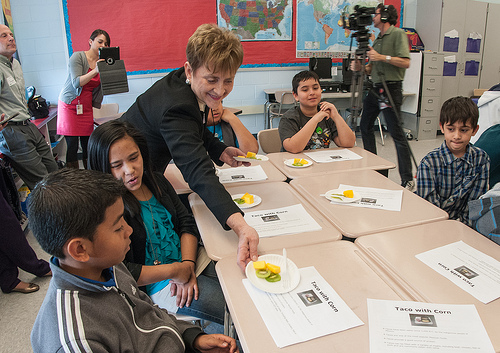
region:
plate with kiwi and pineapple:
[252, 247, 297, 291]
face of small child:
[99, 217, 149, 264]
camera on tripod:
[350, 2, 383, 67]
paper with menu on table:
[262, 296, 359, 333]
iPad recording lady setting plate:
[94, 38, 137, 86]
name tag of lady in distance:
[70, 100, 90, 112]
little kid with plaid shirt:
[425, 70, 472, 208]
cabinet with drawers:
[419, 51, 446, 118]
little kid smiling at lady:
[271, 61, 357, 142]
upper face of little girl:
[86, 125, 154, 175]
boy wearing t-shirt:
[272, 68, 358, 150]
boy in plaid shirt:
[415, 96, 495, 226]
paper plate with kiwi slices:
[239, 248, 306, 298]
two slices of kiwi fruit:
[253, 263, 283, 285]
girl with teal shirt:
[95, 122, 194, 284]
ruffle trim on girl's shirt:
[137, 201, 187, 282]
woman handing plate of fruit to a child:
[152, 14, 306, 299]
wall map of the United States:
[215, 1, 293, 44]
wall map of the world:
[294, 3, 388, 59]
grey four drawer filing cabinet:
[409, 46, 447, 146]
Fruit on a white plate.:
[250, 256, 285, 288]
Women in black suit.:
[155, 25, 250, 185]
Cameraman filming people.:
[342, 3, 412, 103]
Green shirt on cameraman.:
[364, 29, 416, 79]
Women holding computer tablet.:
[80, 25, 136, 97]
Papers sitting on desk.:
[399, 233, 491, 280]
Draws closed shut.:
[415, 43, 445, 144]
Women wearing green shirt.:
[129, 118, 210, 308]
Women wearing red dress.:
[57, 26, 97, 135]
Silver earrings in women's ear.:
[170, 53, 195, 88]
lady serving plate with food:
[137, 21, 336, 300]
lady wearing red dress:
[54, 31, 124, 149]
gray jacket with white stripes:
[29, 166, 233, 351]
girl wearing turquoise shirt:
[84, 119, 190, 301]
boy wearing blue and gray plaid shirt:
[419, 93, 496, 199]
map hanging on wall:
[213, 0, 303, 42]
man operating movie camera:
[339, 4, 456, 119]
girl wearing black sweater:
[66, 119, 193, 275]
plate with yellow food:
[249, 251, 319, 311]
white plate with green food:
[237, 244, 301, 294]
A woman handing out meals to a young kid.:
[111, 20, 302, 308]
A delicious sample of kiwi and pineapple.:
[243, 253, 300, 295]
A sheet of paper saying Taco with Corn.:
[365, 295, 496, 352]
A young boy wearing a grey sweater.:
[25, 166, 239, 351]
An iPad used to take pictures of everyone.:
[97, 45, 121, 68]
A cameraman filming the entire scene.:
[339, 0, 421, 190]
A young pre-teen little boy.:
[412, 92, 492, 222]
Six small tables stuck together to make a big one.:
[157, 142, 499, 350]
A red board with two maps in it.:
[62, 0, 404, 79]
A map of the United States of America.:
[214, 0, 293, 43]